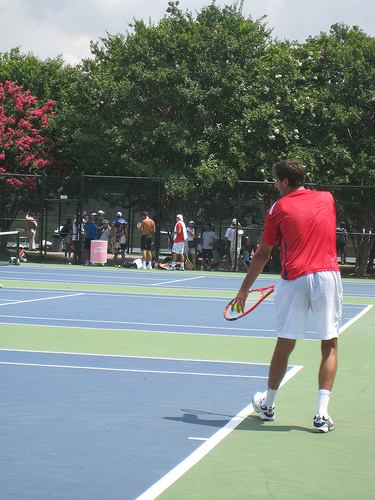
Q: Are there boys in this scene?
A: No, there are no boys.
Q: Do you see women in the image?
A: No, there are no women.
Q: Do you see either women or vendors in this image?
A: No, there are no women or vendors.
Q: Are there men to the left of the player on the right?
A: Yes, there is a man to the left of the player.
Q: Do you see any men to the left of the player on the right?
A: Yes, there is a man to the left of the player.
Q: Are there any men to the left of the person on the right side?
A: Yes, there is a man to the left of the player.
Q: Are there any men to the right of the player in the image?
A: No, the man is to the left of the player.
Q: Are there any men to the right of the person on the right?
A: No, the man is to the left of the player.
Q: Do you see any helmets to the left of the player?
A: No, there is a man to the left of the player.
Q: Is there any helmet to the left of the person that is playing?
A: No, there is a man to the left of the player.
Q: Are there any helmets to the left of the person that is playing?
A: No, there is a man to the left of the player.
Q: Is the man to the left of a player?
A: Yes, the man is to the left of a player.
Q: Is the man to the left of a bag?
A: No, the man is to the left of a player.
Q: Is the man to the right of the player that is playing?
A: No, the man is to the left of the player.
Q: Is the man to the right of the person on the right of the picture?
A: No, the man is to the left of the player.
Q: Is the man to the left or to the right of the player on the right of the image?
A: The man is to the left of the player.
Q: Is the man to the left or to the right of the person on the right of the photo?
A: The man is to the left of the player.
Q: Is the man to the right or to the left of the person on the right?
A: The man is to the left of the player.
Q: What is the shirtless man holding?
A: The man is holding the racket.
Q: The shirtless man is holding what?
A: The man is holding the racket.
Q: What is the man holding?
A: The man is holding the racket.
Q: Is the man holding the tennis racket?
A: Yes, the man is holding the tennis racket.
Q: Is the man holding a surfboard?
A: No, the man is holding the tennis racket.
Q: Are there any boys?
A: No, there are no boys.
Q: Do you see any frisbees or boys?
A: No, there are no boys or frisbees.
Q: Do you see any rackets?
A: Yes, there is a racket.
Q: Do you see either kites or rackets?
A: Yes, there is a racket.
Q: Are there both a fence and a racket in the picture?
A: Yes, there are both a racket and a fence.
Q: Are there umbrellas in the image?
A: No, there are no umbrellas.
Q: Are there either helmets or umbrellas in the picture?
A: No, there are no umbrellas or helmets.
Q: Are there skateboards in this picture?
A: No, there are no skateboards.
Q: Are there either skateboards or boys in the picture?
A: No, there are no skateboards or boys.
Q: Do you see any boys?
A: No, there are no boys.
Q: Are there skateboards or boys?
A: No, there are no boys or skateboards.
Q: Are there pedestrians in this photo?
A: No, there are no pedestrians.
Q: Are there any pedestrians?
A: No, there are no pedestrians.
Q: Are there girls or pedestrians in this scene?
A: No, there are no pedestrians or girls.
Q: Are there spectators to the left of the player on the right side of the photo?
A: Yes, there are spectators to the left of the player.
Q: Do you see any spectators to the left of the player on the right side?
A: Yes, there are spectators to the left of the player.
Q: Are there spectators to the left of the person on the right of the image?
A: Yes, there are spectators to the left of the player.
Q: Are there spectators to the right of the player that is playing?
A: No, the spectators are to the left of the player.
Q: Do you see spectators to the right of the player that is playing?
A: No, the spectators are to the left of the player.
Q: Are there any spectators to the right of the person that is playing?
A: No, the spectators are to the left of the player.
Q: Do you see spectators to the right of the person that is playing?
A: No, the spectators are to the left of the player.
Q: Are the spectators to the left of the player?
A: Yes, the spectators are to the left of the player.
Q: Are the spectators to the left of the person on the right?
A: Yes, the spectators are to the left of the player.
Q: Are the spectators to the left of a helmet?
A: No, the spectators are to the left of the player.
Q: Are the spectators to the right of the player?
A: No, the spectators are to the left of the player.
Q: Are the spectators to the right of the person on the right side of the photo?
A: No, the spectators are to the left of the player.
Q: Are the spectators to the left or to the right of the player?
A: The spectators are to the left of the player.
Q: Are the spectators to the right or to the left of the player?
A: The spectators are to the left of the player.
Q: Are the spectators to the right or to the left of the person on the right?
A: The spectators are to the left of the player.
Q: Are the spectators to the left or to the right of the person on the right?
A: The spectators are to the left of the player.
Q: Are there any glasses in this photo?
A: No, there are no glasses.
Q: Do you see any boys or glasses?
A: No, there are no glasses or boys.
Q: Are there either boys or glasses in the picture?
A: No, there are no glasses or boys.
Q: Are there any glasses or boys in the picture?
A: No, there are no glasses or boys.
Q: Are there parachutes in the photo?
A: No, there are no parachutes.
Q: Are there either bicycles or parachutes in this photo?
A: No, there are no parachutes or bicycles.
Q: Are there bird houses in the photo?
A: No, there are no bird houses.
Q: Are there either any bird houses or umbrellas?
A: No, there are no bird houses or umbrellas.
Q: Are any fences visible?
A: Yes, there is a fence.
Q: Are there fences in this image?
A: Yes, there is a fence.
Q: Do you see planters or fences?
A: Yes, there is a fence.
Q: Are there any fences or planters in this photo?
A: Yes, there is a fence.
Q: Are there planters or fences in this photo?
A: Yes, there is a fence.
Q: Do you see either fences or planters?
A: Yes, there is a fence.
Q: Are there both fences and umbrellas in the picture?
A: No, there is a fence but no umbrellas.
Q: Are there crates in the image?
A: No, there are no crates.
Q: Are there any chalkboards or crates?
A: No, there are no crates or chalkboards.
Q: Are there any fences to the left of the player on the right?
A: Yes, there is a fence to the left of the player.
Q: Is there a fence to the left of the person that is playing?
A: Yes, there is a fence to the left of the player.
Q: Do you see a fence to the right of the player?
A: No, the fence is to the left of the player.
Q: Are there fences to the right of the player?
A: No, the fence is to the left of the player.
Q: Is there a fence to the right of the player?
A: No, the fence is to the left of the player.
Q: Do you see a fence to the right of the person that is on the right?
A: No, the fence is to the left of the player.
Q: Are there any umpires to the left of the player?
A: No, there is a fence to the left of the player.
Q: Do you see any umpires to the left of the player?
A: No, there is a fence to the left of the player.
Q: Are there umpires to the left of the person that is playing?
A: No, there is a fence to the left of the player.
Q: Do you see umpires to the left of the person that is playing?
A: No, there is a fence to the left of the player.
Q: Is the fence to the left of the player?
A: Yes, the fence is to the left of the player.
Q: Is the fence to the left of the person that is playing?
A: Yes, the fence is to the left of the player.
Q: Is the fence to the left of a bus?
A: No, the fence is to the left of the player.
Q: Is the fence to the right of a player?
A: No, the fence is to the left of a player.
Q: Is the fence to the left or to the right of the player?
A: The fence is to the left of the player.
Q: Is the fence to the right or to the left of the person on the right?
A: The fence is to the left of the player.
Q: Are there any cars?
A: No, there are no cars.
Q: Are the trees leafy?
A: Yes, the trees are leafy.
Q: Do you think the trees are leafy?
A: Yes, the trees are leafy.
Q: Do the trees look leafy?
A: Yes, the trees are leafy.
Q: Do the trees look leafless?
A: No, the trees are leafy.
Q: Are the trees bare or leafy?
A: The trees are leafy.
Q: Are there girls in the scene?
A: No, there are no girls.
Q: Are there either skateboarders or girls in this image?
A: No, there are no girls or skateboarders.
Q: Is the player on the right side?
A: Yes, the player is on the right of the image.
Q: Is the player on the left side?
A: No, the player is on the right of the image.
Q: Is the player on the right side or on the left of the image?
A: The player is on the right of the image.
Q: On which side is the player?
A: The player is on the right of the image.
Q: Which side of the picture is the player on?
A: The player is on the right of the image.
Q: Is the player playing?
A: Yes, the player is playing.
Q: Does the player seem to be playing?
A: Yes, the player is playing.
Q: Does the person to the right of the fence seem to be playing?
A: Yes, the player is playing.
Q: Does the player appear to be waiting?
A: No, the player is playing.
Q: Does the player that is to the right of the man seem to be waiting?
A: No, the player is playing.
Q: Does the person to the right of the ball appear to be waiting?
A: No, the player is playing.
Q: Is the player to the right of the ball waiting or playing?
A: The player is playing.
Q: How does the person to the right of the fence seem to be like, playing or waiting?
A: The player is playing.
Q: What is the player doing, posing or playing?
A: The player is playing.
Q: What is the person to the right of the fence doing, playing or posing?
A: The player is playing.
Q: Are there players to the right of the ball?
A: Yes, there is a player to the right of the ball.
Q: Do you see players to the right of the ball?
A: Yes, there is a player to the right of the ball.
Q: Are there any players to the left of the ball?
A: No, the player is to the right of the ball.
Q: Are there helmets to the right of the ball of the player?
A: No, there is a player to the right of the ball.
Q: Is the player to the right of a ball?
A: Yes, the player is to the right of a ball.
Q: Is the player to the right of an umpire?
A: No, the player is to the right of a ball.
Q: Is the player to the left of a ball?
A: No, the player is to the right of a ball.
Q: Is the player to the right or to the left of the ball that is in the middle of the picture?
A: The player is to the right of the ball.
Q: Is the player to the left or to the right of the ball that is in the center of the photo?
A: The player is to the right of the ball.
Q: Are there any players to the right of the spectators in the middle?
A: Yes, there is a player to the right of the spectators.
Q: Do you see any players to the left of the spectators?
A: No, the player is to the right of the spectators.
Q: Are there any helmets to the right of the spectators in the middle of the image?
A: No, there is a player to the right of the spectators.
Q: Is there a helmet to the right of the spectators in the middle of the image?
A: No, there is a player to the right of the spectators.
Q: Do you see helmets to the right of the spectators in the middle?
A: No, there is a player to the right of the spectators.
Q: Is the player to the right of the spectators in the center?
A: Yes, the player is to the right of the spectators.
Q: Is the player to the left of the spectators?
A: No, the player is to the right of the spectators.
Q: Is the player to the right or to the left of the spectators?
A: The player is to the right of the spectators.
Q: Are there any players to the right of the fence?
A: Yes, there is a player to the right of the fence.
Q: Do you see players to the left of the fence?
A: No, the player is to the right of the fence.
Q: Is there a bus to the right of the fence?
A: No, there is a player to the right of the fence.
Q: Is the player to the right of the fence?
A: Yes, the player is to the right of the fence.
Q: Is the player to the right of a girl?
A: No, the player is to the right of the fence.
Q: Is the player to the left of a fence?
A: No, the player is to the right of a fence.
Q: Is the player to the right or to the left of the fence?
A: The player is to the right of the fence.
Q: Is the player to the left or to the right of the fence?
A: The player is to the right of the fence.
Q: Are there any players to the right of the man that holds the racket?
A: Yes, there is a player to the right of the man.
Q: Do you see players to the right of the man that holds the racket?
A: Yes, there is a player to the right of the man.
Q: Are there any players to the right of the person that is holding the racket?
A: Yes, there is a player to the right of the man.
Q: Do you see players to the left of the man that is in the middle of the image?
A: No, the player is to the right of the man.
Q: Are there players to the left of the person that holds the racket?
A: No, the player is to the right of the man.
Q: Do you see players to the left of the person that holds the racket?
A: No, the player is to the right of the man.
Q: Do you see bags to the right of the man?
A: No, there is a player to the right of the man.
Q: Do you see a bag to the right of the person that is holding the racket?
A: No, there is a player to the right of the man.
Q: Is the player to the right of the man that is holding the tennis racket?
A: Yes, the player is to the right of the man.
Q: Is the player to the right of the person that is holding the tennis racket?
A: Yes, the player is to the right of the man.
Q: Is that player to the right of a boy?
A: No, the player is to the right of the man.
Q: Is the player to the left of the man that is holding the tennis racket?
A: No, the player is to the right of the man.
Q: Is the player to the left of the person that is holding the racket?
A: No, the player is to the right of the man.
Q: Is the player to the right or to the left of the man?
A: The player is to the right of the man.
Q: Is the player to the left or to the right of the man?
A: The player is to the right of the man.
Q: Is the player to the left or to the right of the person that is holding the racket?
A: The player is to the right of the man.